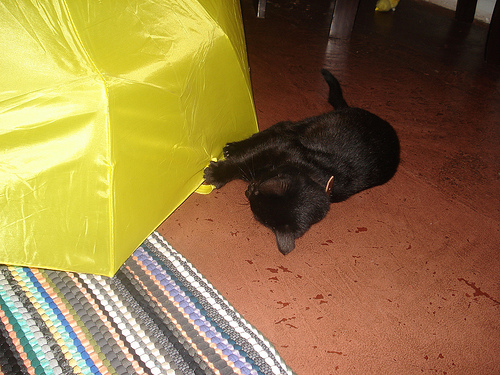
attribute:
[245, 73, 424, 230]
cat — black, playing, laying, small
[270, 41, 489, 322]
floor — red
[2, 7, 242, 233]
umbrella — yellow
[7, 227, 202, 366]
mat — blue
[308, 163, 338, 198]
collar — pink